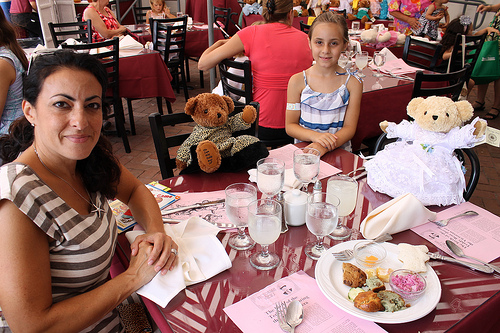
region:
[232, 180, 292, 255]
glasses filled with water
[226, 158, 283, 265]
water glasses sitting on top of a table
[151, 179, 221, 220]
paper laying on top of the table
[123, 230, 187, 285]
a woman's hand placed on top of napkin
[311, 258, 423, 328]
a plate of food placed on a table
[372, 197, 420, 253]
a napkin folded on the table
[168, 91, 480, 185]
two bears sitting at the table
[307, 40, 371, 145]
a kids standing at the table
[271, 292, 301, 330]
silverware placed on top of the paper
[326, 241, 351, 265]
a fork placed on top of a plate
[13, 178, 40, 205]
brown stripe on shirt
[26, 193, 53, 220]
brown stripe on shirt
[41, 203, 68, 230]
brown stripe on shirt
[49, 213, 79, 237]
brown stripe on shirt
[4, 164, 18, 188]
brown stripe on shirt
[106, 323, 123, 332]
brown stripe on shirt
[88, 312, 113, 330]
brown stripe on shirt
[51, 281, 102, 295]
brown stripe on shirt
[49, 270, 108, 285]
brown stripe on shirt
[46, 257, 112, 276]
brown stripe on shirt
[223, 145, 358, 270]
six glasses of water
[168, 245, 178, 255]
a white gold wedding band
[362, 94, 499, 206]
a tan teddy bear in a white dress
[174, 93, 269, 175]
a dressed brown teddy bear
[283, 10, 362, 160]
a girl standing at the table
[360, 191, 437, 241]
a cloth napkin on the table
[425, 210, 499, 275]
sterling silver dinnerware on the table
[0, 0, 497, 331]
customers sitting at tables inside a restaurant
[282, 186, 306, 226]
a white sugar bowl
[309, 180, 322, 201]
salt in a shaker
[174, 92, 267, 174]
a fuzzy brown teddy bear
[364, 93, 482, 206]
a tan teddy bear wearing a white dress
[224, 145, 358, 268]
six glasses of ice cold water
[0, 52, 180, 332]
a dark haired woman wearing a silver necklace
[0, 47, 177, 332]
a woman wearing a wedding band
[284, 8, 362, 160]
a little girl wearing a sun dress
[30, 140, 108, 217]
a silver starfish necklace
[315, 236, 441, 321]
a white plate full of food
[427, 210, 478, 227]
a silver fork sitting on the table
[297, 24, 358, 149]
girl at the table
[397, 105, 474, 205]
teddy bear at table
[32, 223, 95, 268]
the shirt is striped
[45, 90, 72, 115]
eye of the woman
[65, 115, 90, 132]
nose of the woman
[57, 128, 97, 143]
mouth of the woman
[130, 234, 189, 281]
hands of the woman